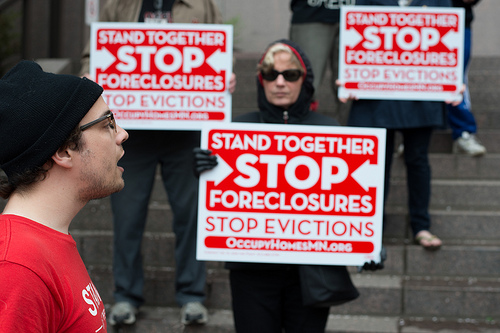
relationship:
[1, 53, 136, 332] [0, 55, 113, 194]
man wearing cap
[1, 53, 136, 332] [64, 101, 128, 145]
man wearing glasses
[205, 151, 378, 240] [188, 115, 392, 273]
protest on sign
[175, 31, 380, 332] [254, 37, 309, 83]
woman has hair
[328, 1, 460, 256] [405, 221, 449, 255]
woman wearing flip flop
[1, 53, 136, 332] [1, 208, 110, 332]
man wearing shirt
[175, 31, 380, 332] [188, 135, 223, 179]
woman wearing glove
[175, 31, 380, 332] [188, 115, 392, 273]
woman holding sign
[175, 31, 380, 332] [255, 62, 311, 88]
woman wearing sunglasses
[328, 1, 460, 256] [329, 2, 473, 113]
woman holding sign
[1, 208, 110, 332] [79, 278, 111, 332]
shirt has writing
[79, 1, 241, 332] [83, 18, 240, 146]
man holding sign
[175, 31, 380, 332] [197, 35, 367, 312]
woman wearing jacket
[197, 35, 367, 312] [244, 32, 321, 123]
jacket has hood